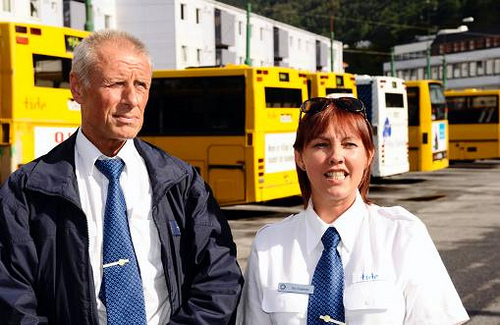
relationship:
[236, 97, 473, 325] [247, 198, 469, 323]
person wearing shirt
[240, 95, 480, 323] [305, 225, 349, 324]
person wearing blue tie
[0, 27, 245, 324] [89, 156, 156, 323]
man wearing tie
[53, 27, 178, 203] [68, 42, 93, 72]
man has hair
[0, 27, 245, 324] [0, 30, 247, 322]
man has black jacket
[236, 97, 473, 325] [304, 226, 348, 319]
person wearing a tie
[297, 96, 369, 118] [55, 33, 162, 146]
glasses on top of head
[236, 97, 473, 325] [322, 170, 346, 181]
person clenching her teeth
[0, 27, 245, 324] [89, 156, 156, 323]
man wearing a tie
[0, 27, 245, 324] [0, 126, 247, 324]
man wearing black jacket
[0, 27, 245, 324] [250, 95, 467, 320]
man and a woman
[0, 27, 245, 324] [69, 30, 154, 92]
man has gray hair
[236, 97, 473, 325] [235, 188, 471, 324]
person has shirt